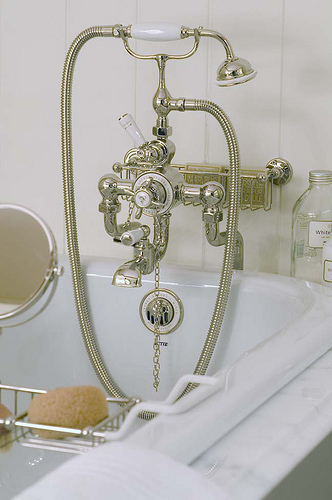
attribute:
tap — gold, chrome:
[116, 221, 155, 251]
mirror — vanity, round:
[1, 205, 59, 327]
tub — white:
[0, 244, 331, 498]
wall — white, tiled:
[0, 1, 330, 277]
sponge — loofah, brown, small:
[25, 384, 113, 437]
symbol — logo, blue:
[137, 194, 148, 207]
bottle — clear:
[287, 168, 331, 280]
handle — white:
[115, 112, 156, 163]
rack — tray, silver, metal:
[0, 371, 225, 450]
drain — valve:
[142, 285, 182, 334]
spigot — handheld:
[117, 17, 257, 91]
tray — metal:
[157, 153, 298, 210]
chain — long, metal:
[149, 264, 165, 391]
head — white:
[213, 53, 258, 89]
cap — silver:
[305, 168, 331, 184]